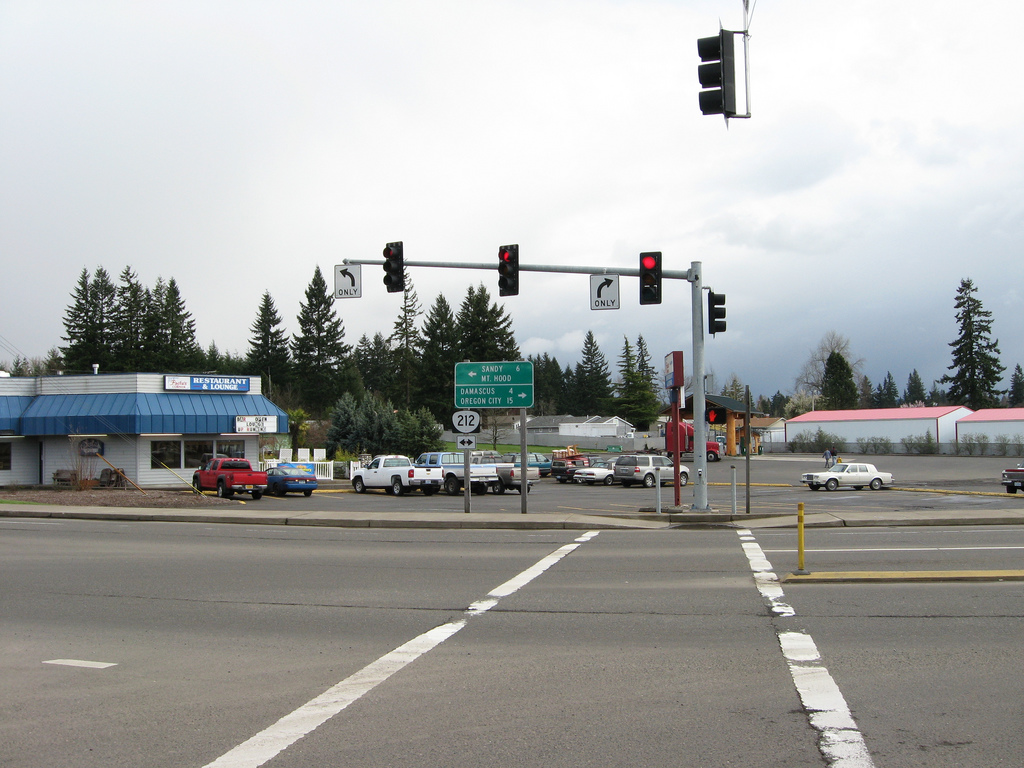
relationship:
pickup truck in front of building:
[192, 457, 268, 500] [2, 367, 296, 489]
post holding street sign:
[507, 405, 536, 527] [446, 354, 542, 519]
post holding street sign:
[453, 414, 488, 512] [446, 354, 542, 519]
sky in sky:
[0, 0, 1024, 410] [0, 4, 1014, 411]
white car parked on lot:
[797, 452, 900, 506] [6, 449, 1020, 523]